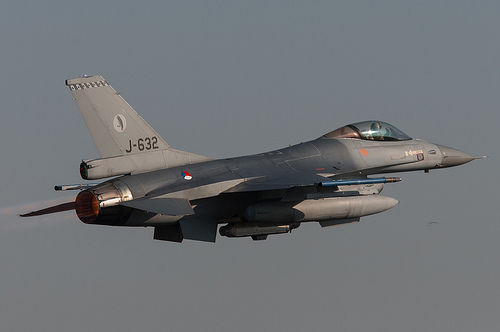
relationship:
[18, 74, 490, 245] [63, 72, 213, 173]
jet has tail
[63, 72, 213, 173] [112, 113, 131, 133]
tail has circle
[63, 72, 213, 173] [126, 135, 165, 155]
tail has writing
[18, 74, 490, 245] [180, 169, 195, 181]
jet has marking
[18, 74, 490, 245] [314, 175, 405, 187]
jet has weapon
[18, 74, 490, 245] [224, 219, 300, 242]
jet has weapon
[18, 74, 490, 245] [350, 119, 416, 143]
jet has hatch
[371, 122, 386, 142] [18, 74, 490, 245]
pilot inside jet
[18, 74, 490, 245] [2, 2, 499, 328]
jet in sky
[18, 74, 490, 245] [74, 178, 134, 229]
jet has engine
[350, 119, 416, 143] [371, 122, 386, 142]
hatch above pilot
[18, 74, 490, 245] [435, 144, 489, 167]
jet has nose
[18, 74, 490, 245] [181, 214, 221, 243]
jet has fin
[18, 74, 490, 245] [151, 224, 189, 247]
jet has fin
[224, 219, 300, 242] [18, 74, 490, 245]
weapon beneath jet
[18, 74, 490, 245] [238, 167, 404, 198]
jet has wing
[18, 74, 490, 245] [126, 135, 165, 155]
jet has writing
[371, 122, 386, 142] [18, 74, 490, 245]
pilot in jet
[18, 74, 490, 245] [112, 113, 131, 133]
jet has circle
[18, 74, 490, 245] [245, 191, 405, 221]
jet has fuel tank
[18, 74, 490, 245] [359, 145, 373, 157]
jet has spot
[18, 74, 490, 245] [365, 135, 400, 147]
jet has cockpit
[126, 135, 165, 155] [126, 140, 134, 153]
writing has letter